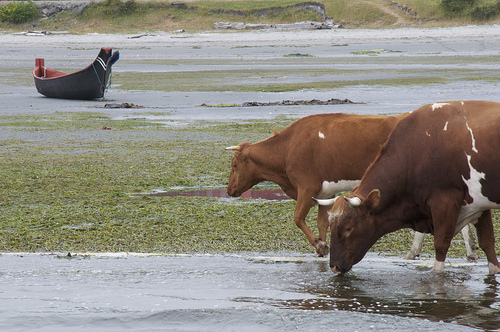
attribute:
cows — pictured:
[213, 87, 475, 300]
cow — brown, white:
[300, 103, 497, 295]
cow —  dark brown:
[170, 57, 498, 310]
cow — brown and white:
[313, 97, 499, 284]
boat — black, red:
[26, 42, 126, 106]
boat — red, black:
[31, 44, 119, 101]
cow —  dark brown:
[224, 110, 474, 262]